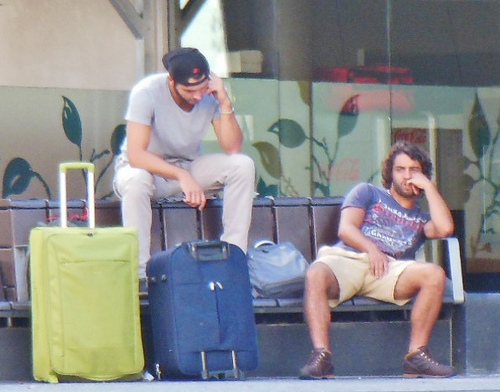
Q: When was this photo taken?
A: Yesterday.